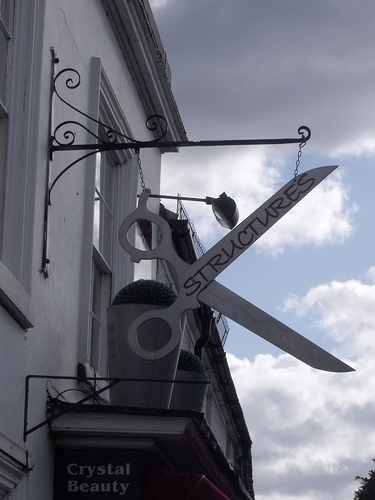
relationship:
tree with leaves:
[349, 452, 374, 499] [350, 452, 374, 497]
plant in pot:
[110, 281, 178, 305] [106, 299, 188, 411]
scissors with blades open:
[117, 164, 359, 375] [203, 165, 354, 379]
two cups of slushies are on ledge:
[105, 278, 212, 415] [48, 393, 259, 497]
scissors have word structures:
[117, 164, 359, 375] [185, 173, 315, 295]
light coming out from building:
[93, 144, 106, 257] [1, 1, 192, 499]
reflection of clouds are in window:
[93, 144, 106, 257] [80, 55, 116, 400]